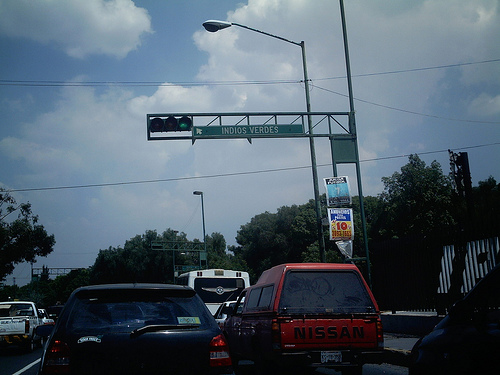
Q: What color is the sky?
A: Blue.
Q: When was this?
A: Daytime.